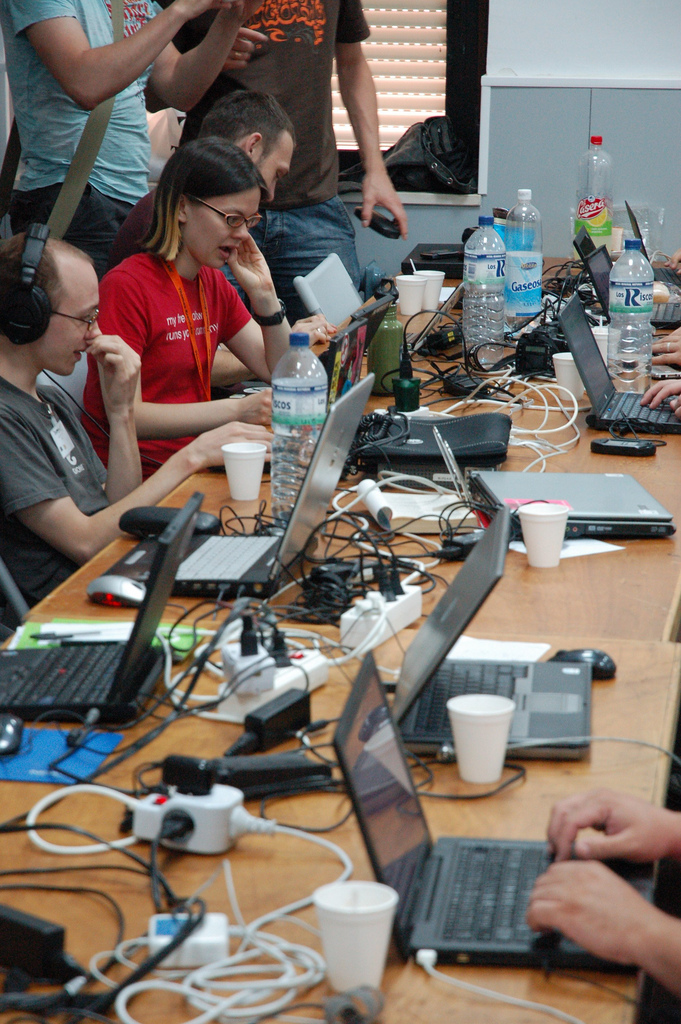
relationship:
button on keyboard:
[458, 913, 470, 922] [441, 840, 559, 938]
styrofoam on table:
[444, 693, 514, 783] [2, 618, 680, 1022]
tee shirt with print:
[82, 248, 252, 481] [162, 307, 220, 342]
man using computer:
[522, 785, 678, 1000] [329, 651, 655, 977]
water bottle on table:
[266, 333, 327, 533] [18, 255, 678, 642]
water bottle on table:
[460, 212, 503, 351] [18, 255, 678, 642]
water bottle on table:
[500, 183, 539, 334] [18, 255, 678, 642]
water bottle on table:
[605, 236, 650, 394] [18, 255, 678, 642]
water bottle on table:
[577, 127, 609, 257] [18, 255, 678, 642]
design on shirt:
[245, 3, 325, 49] [146, 1, 370, 212]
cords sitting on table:
[275, 510, 453, 623] [18, 255, 678, 642]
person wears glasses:
[2, 230, 276, 601] [51, 306, 99, 330]